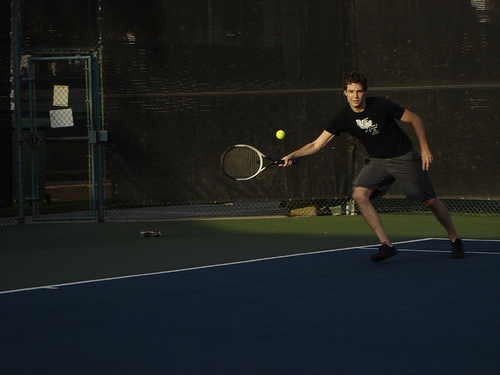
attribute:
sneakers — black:
[373, 237, 398, 263]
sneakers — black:
[447, 236, 465, 260]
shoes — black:
[364, 234, 470, 271]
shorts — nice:
[347, 156, 432, 198]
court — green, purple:
[6, 219, 472, 374]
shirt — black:
[323, 97, 413, 159]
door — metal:
[16, 33, 116, 250]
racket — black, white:
[186, 141, 277, 196]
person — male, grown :
[281, 74, 471, 264]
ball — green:
[268, 125, 287, 139]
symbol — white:
[354, 115, 378, 134]